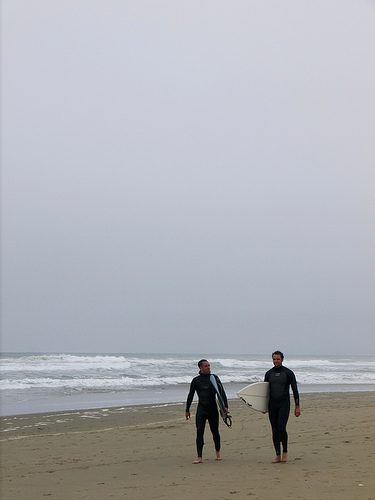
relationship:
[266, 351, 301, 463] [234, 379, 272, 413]
man carrying board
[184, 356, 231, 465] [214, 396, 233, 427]
man carrying board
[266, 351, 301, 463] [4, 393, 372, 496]
man on beach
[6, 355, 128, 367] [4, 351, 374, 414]
wave in ocean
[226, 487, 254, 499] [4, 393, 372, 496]
footprints on sand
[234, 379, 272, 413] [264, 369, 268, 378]
board under arm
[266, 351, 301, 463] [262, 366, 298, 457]
man wearing wetsuit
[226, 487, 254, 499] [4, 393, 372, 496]
footprints in sand